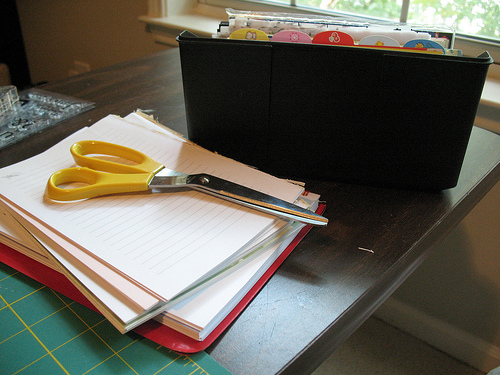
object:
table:
[0, 45, 500, 375]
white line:
[359, 247, 373, 254]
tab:
[311, 30, 353, 44]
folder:
[173, 11, 493, 199]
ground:
[447, 233, 499, 315]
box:
[176, 15, 491, 192]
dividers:
[188, 12, 480, 60]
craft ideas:
[212, 3, 437, 28]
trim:
[372, 295, 498, 373]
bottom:
[369, 299, 499, 372]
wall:
[0, 0, 175, 85]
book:
[0, 108, 323, 354]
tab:
[356, 36, 400, 49]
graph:
[0, 251, 228, 374]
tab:
[404, 39, 446, 50]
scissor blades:
[43, 138, 329, 227]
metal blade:
[149, 166, 329, 227]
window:
[142, 0, 500, 65]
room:
[1, 1, 498, 373]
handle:
[43, 139, 163, 201]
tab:
[275, 31, 314, 46]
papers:
[212, 0, 452, 49]